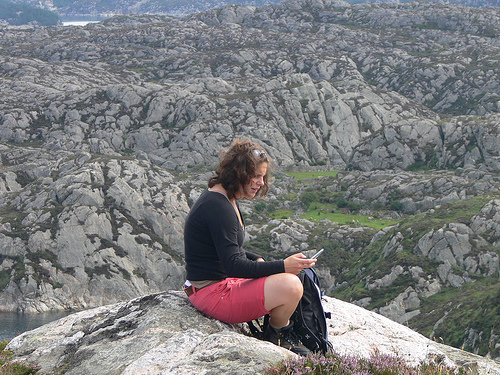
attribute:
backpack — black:
[266, 265, 335, 357]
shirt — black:
[183, 183, 283, 281]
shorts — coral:
[181, 277, 270, 324]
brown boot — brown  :
[259, 316, 319, 357]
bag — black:
[289, 258, 337, 353]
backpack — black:
[271, 254, 341, 360]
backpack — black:
[287, 261, 330, 358]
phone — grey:
[297, 245, 328, 263]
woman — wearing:
[183, 128, 303, 343]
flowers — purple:
[274, 349, 477, 374]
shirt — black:
[177, 187, 260, 272]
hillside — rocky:
[39, 121, 140, 271]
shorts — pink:
[183, 275, 273, 326]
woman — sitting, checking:
[183, 137, 316, 359]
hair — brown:
[202, 140, 269, 198]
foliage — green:
[282, 163, 499, 335]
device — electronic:
[308, 245, 325, 259]